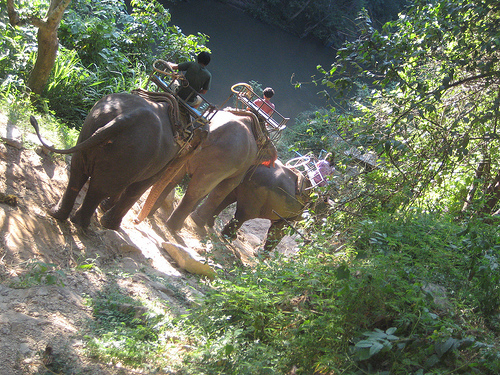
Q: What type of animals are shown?
A: Elephants.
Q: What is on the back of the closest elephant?
A: A person.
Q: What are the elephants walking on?
A: Dirt path.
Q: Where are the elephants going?
A: Downhill.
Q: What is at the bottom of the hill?
A: Water.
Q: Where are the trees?
A: Beside the path.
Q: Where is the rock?
A: In the path.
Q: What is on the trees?
A: Green leaves.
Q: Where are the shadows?
A: Ground.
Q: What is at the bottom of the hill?
A: Water.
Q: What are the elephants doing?
A: Walking.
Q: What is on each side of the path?
A: Trees.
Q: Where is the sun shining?
A: Through the trees.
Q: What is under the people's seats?
A: Blankets.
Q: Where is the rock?
A: On the path.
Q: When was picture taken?
A: Daytime.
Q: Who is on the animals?
A: People.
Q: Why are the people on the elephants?
A: Traveling.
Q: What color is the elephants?
A: Grey.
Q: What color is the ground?
A: Brown.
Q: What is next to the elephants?
A: Trees.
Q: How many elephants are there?
A: Three.